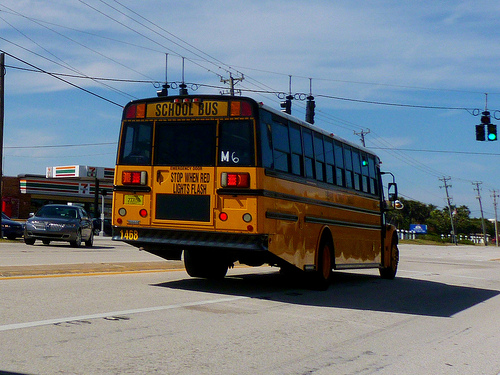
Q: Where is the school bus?
A: On the road.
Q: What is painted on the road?
A: White street lines.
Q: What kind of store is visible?
A: A convenience store.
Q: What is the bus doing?
A: Driving on the road.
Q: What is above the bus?
A: Traffic lights.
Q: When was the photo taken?
A: During the daytime.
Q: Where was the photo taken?
A: The road.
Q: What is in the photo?
A: Bus.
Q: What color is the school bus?
A: Yellow.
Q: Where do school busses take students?
A: School.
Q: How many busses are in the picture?
A: One.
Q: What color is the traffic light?
A: Green.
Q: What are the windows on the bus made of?
A: Glass.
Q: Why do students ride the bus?
A: To get to school.